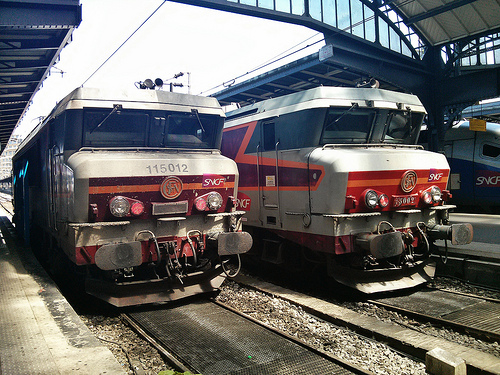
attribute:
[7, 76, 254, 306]
train engine — red, white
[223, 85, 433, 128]
roof — white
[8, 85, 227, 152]
roof — white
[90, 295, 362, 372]
track — black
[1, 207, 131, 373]
sidewalk — grey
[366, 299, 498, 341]
track — set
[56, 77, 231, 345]
train — grey, orange, red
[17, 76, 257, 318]
train — old